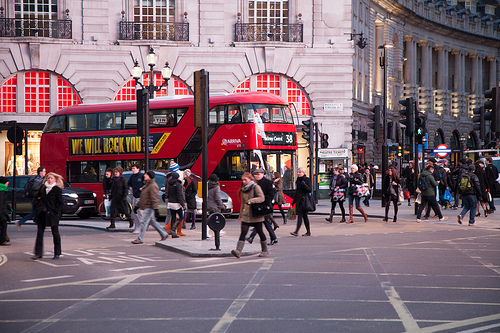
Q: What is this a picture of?
A: Bus.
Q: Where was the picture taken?
A: Street.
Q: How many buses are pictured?
A: 1.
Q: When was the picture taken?
A: Afternoon.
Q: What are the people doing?
A: Walking.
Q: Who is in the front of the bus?
A: Driver.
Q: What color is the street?
A: Grey.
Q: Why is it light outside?
A: Sun.